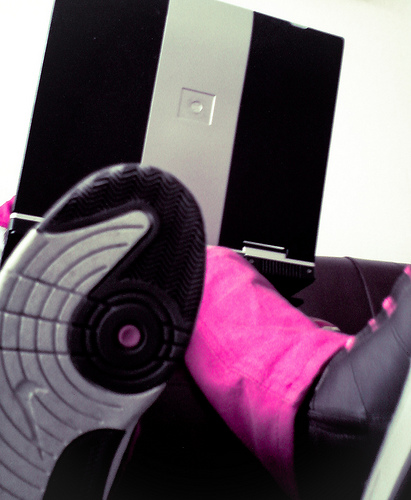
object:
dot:
[117, 324, 141, 348]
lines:
[0, 455, 45, 495]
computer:
[0, 0, 346, 302]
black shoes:
[293, 265, 411, 498]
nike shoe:
[0, 159, 209, 498]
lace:
[402, 260, 411, 281]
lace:
[343, 333, 358, 354]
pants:
[185, 242, 356, 497]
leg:
[179, 241, 363, 498]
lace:
[381, 294, 398, 319]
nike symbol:
[13, 376, 52, 463]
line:
[0, 302, 72, 329]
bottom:
[0, 162, 210, 498]